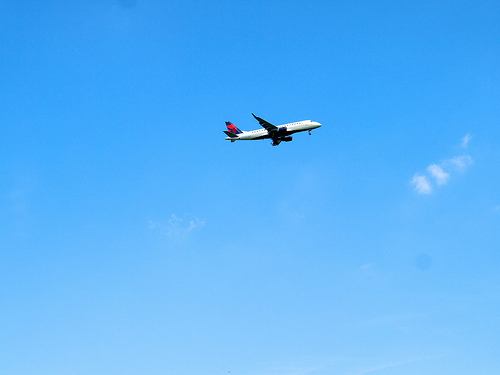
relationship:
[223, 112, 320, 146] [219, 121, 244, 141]
airplane with accents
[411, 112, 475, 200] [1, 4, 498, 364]
clouds at bottom sky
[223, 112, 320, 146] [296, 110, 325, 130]
airplane with nose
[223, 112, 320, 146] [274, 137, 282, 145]
airplane with wheel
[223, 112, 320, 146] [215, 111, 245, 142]
airplane with accents